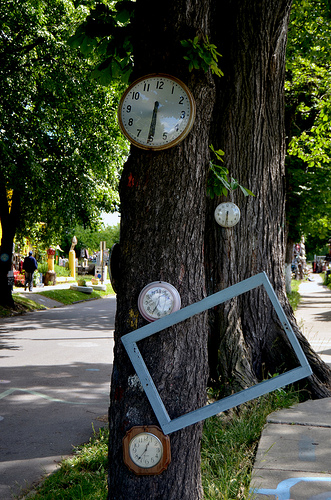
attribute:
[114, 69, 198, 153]
clock — brown, big, large, white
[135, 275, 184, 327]
clock — pink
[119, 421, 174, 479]
clock — brown, wood, wooden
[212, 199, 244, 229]
clock — small, smallest